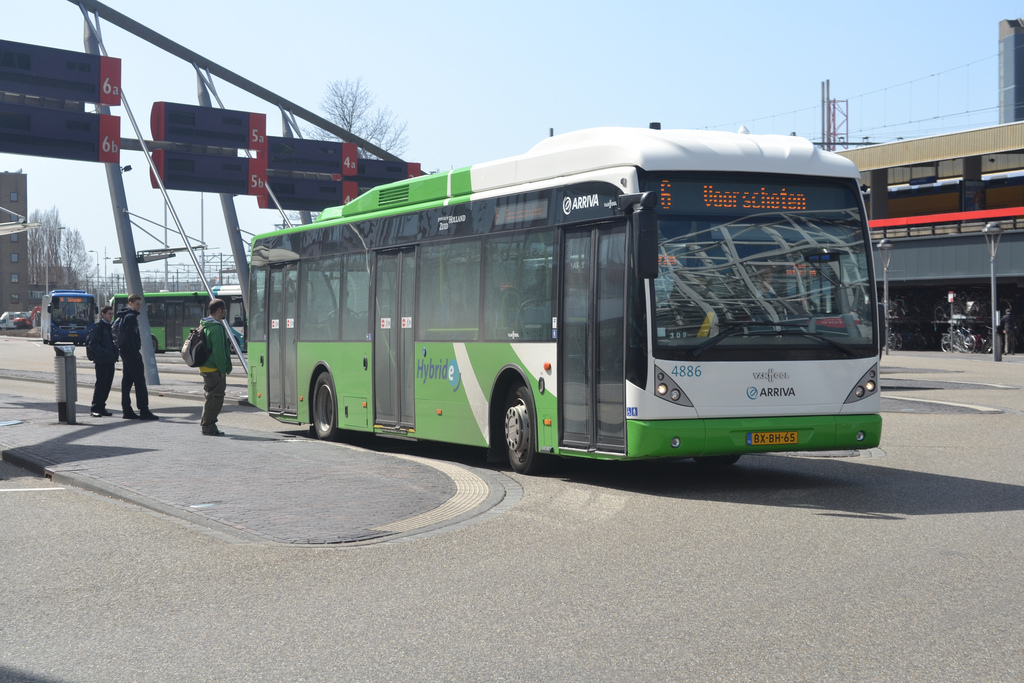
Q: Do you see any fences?
A: No, there are no fences.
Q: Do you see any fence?
A: No, there are no fences.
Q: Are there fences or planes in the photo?
A: No, there are no fences or planes.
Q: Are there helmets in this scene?
A: No, there are no helmets.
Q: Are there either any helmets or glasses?
A: No, there are no helmets or glasses.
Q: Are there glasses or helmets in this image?
A: No, there are no helmets or glasses.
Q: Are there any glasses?
A: No, there are no glasses.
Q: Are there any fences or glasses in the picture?
A: No, there are no glasses or fences.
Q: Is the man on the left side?
A: Yes, the man is on the left of the image.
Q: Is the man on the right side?
A: No, the man is on the left of the image.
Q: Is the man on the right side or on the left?
A: The man is on the left of the image.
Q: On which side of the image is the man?
A: The man is on the left of the image.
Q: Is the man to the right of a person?
A: Yes, the man is to the right of a person.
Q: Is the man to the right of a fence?
A: No, the man is to the right of a person.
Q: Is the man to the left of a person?
A: No, the man is to the right of a person.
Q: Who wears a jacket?
A: The man wears a jacket.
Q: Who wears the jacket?
A: The man wears a jacket.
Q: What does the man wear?
A: The man wears a jacket.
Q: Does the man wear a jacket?
A: Yes, the man wears a jacket.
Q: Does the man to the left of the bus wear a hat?
A: No, the man wears a jacket.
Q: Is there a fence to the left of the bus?
A: No, there is a man to the left of the bus.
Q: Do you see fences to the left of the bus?
A: No, there is a man to the left of the bus.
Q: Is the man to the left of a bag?
A: No, the man is to the left of the bus.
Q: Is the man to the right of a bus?
A: No, the man is to the left of a bus.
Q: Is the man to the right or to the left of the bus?
A: The man is to the left of the bus.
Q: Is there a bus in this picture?
A: Yes, there is a bus.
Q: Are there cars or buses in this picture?
A: Yes, there is a bus.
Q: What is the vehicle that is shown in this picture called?
A: The vehicle is a bus.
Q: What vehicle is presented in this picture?
A: The vehicle is a bus.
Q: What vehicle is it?
A: The vehicle is a bus.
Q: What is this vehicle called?
A: This is a bus.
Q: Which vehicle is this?
A: This is a bus.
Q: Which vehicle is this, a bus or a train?
A: This is a bus.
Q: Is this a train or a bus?
A: This is a bus.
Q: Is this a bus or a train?
A: This is a bus.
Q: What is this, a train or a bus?
A: This is a bus.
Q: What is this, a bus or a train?
A: This is a bus.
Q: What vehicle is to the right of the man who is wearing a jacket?
A: The vehicle is a bus.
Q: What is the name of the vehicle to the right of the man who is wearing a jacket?
A: The vehicle is a bus.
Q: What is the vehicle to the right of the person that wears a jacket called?
A: The vehicle is a bus.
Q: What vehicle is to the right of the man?
A: The vehicle is a bus.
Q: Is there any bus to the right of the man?
A: Yes, there is a bus to the right of the man.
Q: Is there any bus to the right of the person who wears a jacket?
A: Yes, there is a bus to the right of the man.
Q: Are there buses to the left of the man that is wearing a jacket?
A: No, the bus is to the right of the man.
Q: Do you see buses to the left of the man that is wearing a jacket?
A: No, the bus is to the right of the man.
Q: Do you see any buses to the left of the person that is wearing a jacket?
A: No, the bus is to the right of the man.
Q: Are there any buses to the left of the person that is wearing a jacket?
A: No, the bus is to the right of the man.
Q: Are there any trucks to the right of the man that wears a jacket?
A: No, there is a bus to the right of the man.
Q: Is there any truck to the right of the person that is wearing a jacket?
A: No, there is a bus to the right of the man.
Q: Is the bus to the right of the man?
A: Yes, the bus is to the right of the man.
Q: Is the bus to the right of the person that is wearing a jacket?
A: Yes, the bus is to the right of the man.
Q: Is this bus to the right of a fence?
A: No, the bus is to the right of the man.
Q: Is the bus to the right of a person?
A: Yes, the bus is to the right of a person.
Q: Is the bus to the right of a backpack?
A: No, the bus is to the right of a person.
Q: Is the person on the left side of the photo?
A: Yes, the person is on the left of the image.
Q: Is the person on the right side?
A: No, the person is on the left of the image.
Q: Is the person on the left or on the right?
A: The person is on the left of the image.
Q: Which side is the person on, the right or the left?
A: The person is on the left of the image.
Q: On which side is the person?
A: The person is on the left of the image.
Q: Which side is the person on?
A: The person is on the left of the image.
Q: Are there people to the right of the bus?
A: No, the person is to the left of the bus.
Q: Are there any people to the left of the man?
A: Yes, there is a person to the left of the man.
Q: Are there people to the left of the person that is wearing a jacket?
A: Yes, there is a person to the left of the man.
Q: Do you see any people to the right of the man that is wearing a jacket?
A: No, the person is to the left of the man.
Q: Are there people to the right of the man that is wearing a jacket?
A: No, the person is to the left of the man.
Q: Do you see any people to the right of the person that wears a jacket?
A: No, the person is to the left of the man.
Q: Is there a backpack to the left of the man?
A: No, there is a person to the left of the man.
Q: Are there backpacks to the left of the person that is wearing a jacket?
A: No, there is a person to the left of the man.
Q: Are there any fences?
A: No, there are no fences.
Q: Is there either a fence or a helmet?
A: No, there are no fences or helmets.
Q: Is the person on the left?
A: Yes, the person is on the left of the image.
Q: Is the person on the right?
A: No, the person is on the left of the image.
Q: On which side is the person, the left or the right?
A: The person is on the left of the image.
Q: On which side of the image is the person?
A: The person is on the left of the image.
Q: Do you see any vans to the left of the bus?
A: No, there is a person to the left of the bus.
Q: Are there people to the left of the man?
A: Yes, there is a person to the left of the man.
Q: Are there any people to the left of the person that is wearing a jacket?
A: Yes, there is a person to the left of the man.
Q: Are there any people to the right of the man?
A: No, the person is to the left of the man.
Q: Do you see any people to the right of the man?
A: No, the person is to the left of the man.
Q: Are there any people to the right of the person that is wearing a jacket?
A: No, the person is to the left of the man.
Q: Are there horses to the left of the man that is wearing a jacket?
A: No, there is a person to the left of the man.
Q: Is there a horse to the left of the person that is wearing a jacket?
A: No, there is a person to the left of the man.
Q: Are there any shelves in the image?
A: No, there are no shelves.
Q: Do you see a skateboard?
A: No, there are no skateboards.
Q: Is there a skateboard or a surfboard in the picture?
A: No, there are no skateboards or surfboards.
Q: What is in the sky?
A: The clouds are in the sky.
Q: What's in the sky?
A: The clouds are in the sky.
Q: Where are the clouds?
A: The clouds are in the sky.